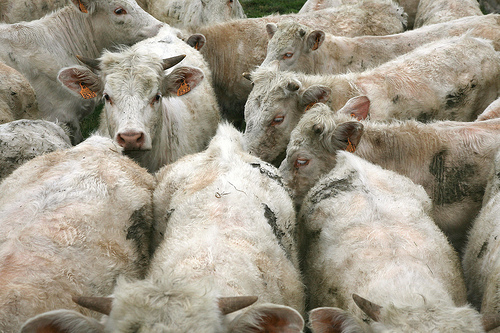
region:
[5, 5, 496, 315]
The cows are grouped close together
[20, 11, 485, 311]
Some cows are waiting for something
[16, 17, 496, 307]
The cows are waiting for food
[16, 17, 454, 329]
The cows are male and female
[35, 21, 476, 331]
Some cows are growing nice horns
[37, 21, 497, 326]
Some cows are watching for predators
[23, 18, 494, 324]
Some cows are looking very nervous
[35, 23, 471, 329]
Some cows are owned by a farmer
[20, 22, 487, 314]
Some cows are wearing ear tags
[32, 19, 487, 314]
The cows are enjoying the day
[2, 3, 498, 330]
Group of white cows in a barn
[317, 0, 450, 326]
Group of white cows in a barn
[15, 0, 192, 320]
Group of white cows in a barn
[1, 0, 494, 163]
Group of white cows in a barn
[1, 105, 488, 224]
Group of white cows in a barn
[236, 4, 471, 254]
Group of white cows in a barn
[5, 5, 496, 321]
Some cows are all grouped together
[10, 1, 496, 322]
The cows belong to a farmer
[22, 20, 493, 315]
The cows are looking for food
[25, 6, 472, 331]
The cows are watching for predators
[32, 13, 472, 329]
Some cows are waiting to be fed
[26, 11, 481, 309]
Some cows are starting to get horns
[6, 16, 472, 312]
The cows are grown for their meat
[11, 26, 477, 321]
The cows are out in the daytime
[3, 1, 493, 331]
White cow together in a barn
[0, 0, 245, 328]
White cow together in a barn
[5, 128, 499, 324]
White cow together in a barn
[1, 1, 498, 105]
White cow together in a barn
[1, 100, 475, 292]
White cow together in a barn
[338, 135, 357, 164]
Yellow tag in a cows ear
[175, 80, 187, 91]
Yellow tag in a cows ear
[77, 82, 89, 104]
Yellow tag in a cows ear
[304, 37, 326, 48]
Yellow tag in a cows ear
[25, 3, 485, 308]
The cows are raised for their meat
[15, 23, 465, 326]
The cows are waiting to be fed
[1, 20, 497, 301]
The cows are owned by a farmer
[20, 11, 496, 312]
The cows are looking very nervous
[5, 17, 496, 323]
The cows are wanting some attention